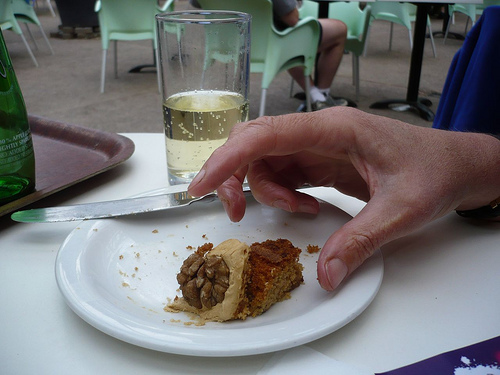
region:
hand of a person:
[190, 52, 494, 284]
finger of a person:
[162, 120, 309, 210]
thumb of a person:
[296, 175, 434, 287]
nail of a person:
[316, 245, 374, 296]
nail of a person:
[185, 168, 215, 192]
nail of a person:
[218, 192, 245, 217]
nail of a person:
[265, 199, 289, 214]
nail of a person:
[296, 202, 320, 212]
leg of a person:
[306, 27, 364, 104]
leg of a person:
[275, 58, 329, 113]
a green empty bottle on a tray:
[1, 30, 36, 205]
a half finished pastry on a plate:
[173, 239, 303, 324]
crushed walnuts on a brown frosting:
[178, 255, 230, 310]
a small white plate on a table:
[54, 190, 384, 355]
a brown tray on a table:
[1, 114, 133, 219]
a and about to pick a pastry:
[193, 105, 498, 289]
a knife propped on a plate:
[11, 184, 302, 224]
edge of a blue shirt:
[433, 3, 499, 133]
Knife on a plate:
[8, 172, 325, 225]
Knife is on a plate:
[5, 175, 327, 234]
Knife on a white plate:
[12, 170, 327, 240]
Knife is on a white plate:
[6, 175, 326, 230]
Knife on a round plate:
[7, 169, 335, 229]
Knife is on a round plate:
[6, 162, 329, 239]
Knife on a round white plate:
[1, 177, 325, 234]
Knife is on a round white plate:
[12, 175, 337, 228]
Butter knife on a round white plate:
[10, 162, 338, 232]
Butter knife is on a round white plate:
[8, 172, 330, 232]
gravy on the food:
[221, 234, 252, 316]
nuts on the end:
[183, 257, 223, 318]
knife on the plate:
[18, 181, 187, 246]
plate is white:
[80, 324, 295, 359]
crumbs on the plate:
[84, 221, 184, 276]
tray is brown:
[51, 132, 122, 172]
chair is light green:
[256, 2, 307, 114]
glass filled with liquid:
[155, 11, 218, 156]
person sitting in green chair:
[263, 0, 350, 108]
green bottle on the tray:
[0, 24, 96, 201]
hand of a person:
[165, 65, 467, 284]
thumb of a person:
[316, 190, 423, 285]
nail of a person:
[320, 255, 355, 280]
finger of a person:
[194, 112, 283, 207]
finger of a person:
[205, 187, 256, 245]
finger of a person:
[253, 185, 290, 220]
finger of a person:
[302, 198, 343, 224]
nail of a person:
[220, 197, 240, 228]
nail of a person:
[269, 200, 301, 215]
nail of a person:
[298, 198, 330, 215]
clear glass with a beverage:
[154, 12, 252, 176]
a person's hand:
[195, 110, 442, 285]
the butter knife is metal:
[8, 180, 282, 222]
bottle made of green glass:
[0, 25, 31, 197]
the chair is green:
[92, 2, 169, 89]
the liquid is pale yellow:
[164, 91, 247, 171]